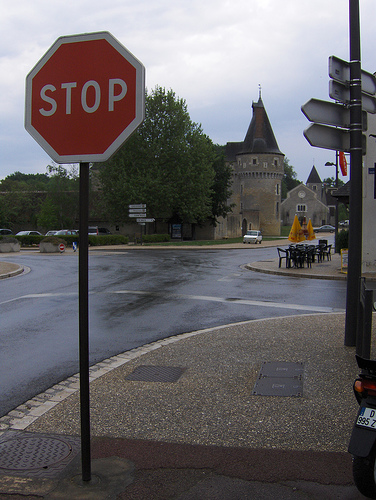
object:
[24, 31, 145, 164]
sign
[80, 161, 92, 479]
pole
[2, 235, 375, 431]
street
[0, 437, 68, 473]
manhole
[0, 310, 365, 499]
sidewalk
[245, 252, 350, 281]
sidewalk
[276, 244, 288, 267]
chair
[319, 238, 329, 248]
chair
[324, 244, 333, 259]
chair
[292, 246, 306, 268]
chair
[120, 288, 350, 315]
line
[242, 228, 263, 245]
car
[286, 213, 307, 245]
umbrella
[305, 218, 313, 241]
umbrella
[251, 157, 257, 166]
window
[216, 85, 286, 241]
building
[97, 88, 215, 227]
tree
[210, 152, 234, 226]
tree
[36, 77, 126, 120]
writing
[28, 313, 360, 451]
gravel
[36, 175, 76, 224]
tree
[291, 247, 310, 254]
table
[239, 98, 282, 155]
roof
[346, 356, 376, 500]
motorcycle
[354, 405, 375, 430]
license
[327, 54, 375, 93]
sign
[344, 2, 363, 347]
pole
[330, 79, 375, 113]
sign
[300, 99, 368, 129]
sign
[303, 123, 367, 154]
sign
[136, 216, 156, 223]
sign